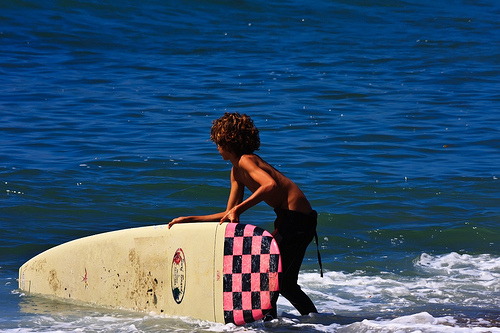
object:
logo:
[168, 246, 187, 305]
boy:
[165, 111, 319, 325]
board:
[18, 221, 285, 326]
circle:
[166, 247, 188, 304]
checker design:
[221, 222, 285, 327]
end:
[222, 222, 283, 327]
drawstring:
[312, 230, 324, 277]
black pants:
[264, 209, 326, 321]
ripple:
[374, 221, 446, 237]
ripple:
[349, 194, 411, 216]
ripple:
[342, 127, 409, 141]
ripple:
[432, 71, 498, 84]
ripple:
[290, 55, 333, 70]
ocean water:
[16, 12, 189, 127]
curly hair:
[208, 111, 263, 156]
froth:
[366, 286, 377, 292]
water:
[0, 0, 499, 333]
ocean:
[0, 0, 500, 333]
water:
[309, 265, 419, 325]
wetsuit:
[231, 151, 321, 309]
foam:
[439, 251, 463, 263]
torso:
[231, 156, 311, 212]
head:
[209, 110, 261, 161]